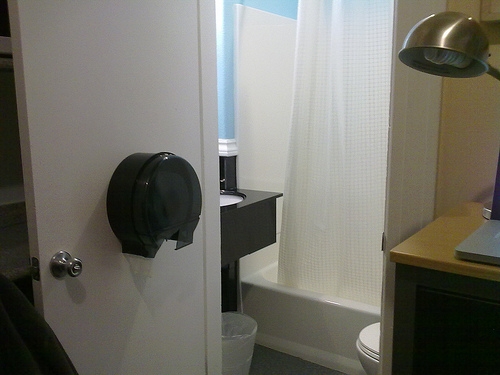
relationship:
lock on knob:
[72, 265, 80, 272] [49, 250, 85, 280]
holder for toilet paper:
[100, 151, 203, 258] [153, 173, 189, 241]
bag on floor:
[221, 312, 258, 375] [248, 341, 349, 374]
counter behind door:
[221, 188, 283, 267] [6, 1, 221, 374]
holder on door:
[100, 151, 203, 258] [6, 1, 221, 374]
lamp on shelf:
[397, 12, 500, 85] [389, 203, 500, 374]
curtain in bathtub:
[277, 2, 394, 308] [239, 263, 381, 375]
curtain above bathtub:
[277, 2, 394, 308] [239, 263, 381, 375]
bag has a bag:
[221, 312, 258, 375] [221, 310, 257, 362]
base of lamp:
[455, 220, 500, 264] [397, 12, 500, 85]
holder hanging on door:
[100, 151, 203, 258] [6, 1, 221, 374]